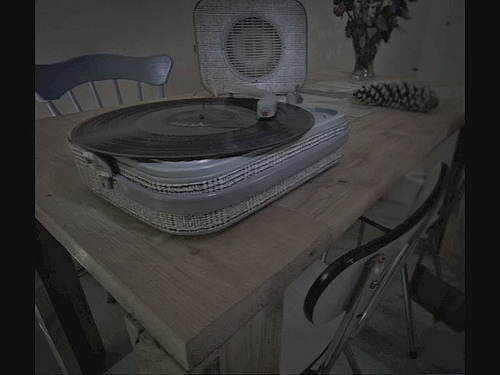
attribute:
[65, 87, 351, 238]
record player — very old, white, black, old, dusty, appearing old, set to 78 rpm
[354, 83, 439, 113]
cone — large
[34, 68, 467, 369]
table — made of wood, wooden, brown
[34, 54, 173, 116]
chair — wooden, white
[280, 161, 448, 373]
chair — metal, black, white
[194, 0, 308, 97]
speaker — in background, small, for listening, old, worn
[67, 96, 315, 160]
record — black, playing, 33 rpm, dusty, 78 size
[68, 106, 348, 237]
lining — gray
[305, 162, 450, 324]
trim — black